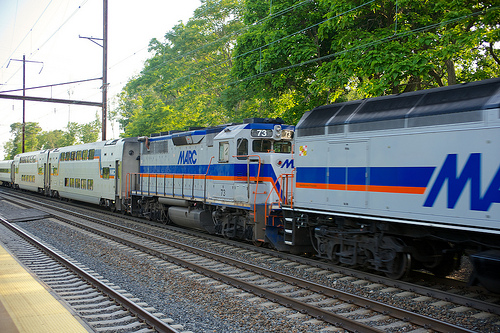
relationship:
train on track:
[4, 65, 495, 280] [337, 254, 483, 308]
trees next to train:
[111, 3, 490, 129] [4, 65, 495, 280]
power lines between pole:
[21, 6, 93, 54] [74, 5, 115, 141]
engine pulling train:
[127, 111, 288, 248] [4, 65, 495, 280]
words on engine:
[173, 151, 205, 169] [127, 111, 288, 248]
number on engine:
[250, 122, 269, 138] [127, 111, 288, 248]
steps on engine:
[256, 171, 302, 253] [127, 111, 288, 248]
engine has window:
[127, 111, 288, 248] [212, 135, 234, 170]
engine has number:
[127, 111, 288, 248] [250, 122, 269, 138]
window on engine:
[212, 135, 234, 170] [127, 111, 288, 248]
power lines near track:
[21, 6, 93, 54] [15, 211, 212, 321]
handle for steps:
[262, 175, 283, 204] [256, 171, 302, 253]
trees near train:
[111, 3, 490, 129] [4, 65, 495, 280]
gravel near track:
[111, 252, 189, 307] [15, 211, 212, 321]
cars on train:
[12, 137, 140, 212] [4, 65, 495, 280]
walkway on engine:
[124, 169, 219, 205] [127, 111, 288, 248]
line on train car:
[287, 161, 438, 186] [288, 78, 495, 279]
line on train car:
[296, 182, 428, 198] [288, 78, 495, 279]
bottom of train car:
[297, 212, 495, 290] [288, 78, 495, 279]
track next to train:
[15, 211, 212, 321] [4, 65, 495, 280]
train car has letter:
[288, 78, 495, 279] [423, 147, 481, 218]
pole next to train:
[74, 5, 115, 141] [4, 65, 495, 280]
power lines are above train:
[21, 6, 93, 54] [4, 65, 495, 280]